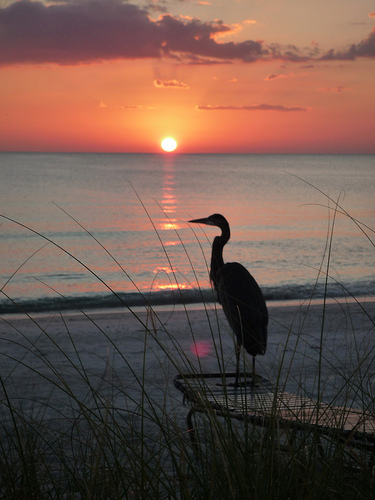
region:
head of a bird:
[188, 204, 233, 240]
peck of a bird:
[190, 208, 211, 224]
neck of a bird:
[208, 227, 233, 255]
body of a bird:
[209, 256, 281, 329]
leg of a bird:
[218, 335, 278, 383]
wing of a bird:
[221, 265, 302, 336]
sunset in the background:
[123, 122, 219, 179]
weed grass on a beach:
[26, 368, 76, 494]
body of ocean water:
[95, 178, 160, 254]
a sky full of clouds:
[107, 15, 254, 60]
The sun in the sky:
[160, 136, 177, 154]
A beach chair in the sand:
[172, 372, 374, 468]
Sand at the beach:
[0, 302, 373, 495]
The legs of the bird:
[233, 340, 257, 386]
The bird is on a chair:
[188, 213, 268, 391]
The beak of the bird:
[190, 216, 207, 225]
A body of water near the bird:
[0, 154, 373, 312]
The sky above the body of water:
[0, 1, 373, 153]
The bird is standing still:
[188, 214, 268, 387]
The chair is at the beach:
[173, 371, 374, 468]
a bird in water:
[161, 168, 316, 381]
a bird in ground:
[177, 208, 300, 399]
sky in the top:
[133, 221, 217, 306]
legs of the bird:
[224, 358, 273, 401]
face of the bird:
[173, 179, 257, 253]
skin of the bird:
[231, 280, 255, 315]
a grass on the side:
[61, 351, 356, 491]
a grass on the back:
[35, 295, 326, 498]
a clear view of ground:
[38, 285, 250, 382]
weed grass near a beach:
[1, 412, 41, 493]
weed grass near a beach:
[68, 415, 118, 492]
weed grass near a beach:
[120, 413, 166, 494]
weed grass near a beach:
[171, 406, 212, 498]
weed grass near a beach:
[216, 399, 255, 496]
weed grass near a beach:
[249, 370, 298, 494]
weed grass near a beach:
[268, 370, 328, 498]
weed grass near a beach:
[308, 385, 361, 493]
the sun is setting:
[39, 85, 349, 258]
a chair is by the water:
[170, 339, 348, 449]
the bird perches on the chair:
[176, 200, 337, 407]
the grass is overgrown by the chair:
[29, 309, 301, 461]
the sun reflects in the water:
[90, 239, 321, 458]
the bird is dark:
[180, 205, 287, 367]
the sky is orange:
[61, 69, 233, 178]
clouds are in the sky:
[63, 15, 358, 110]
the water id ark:
[34, 334, 85, 392]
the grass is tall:
[55, 322, 234, 482]